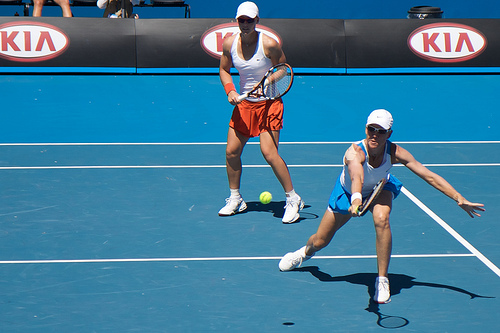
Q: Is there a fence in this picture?
A: No, there are no fences.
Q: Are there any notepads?
A: No, there are no notepads.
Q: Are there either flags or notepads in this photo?
A: No, there are no notepads or flags.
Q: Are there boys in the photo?
A: No, there are no boys.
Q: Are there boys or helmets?
A: No, there are no boys or helmets.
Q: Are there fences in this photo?
A: No, there are no fences.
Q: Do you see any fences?
A: No, there are no fences.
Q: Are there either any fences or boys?
A: No, there are no fences or boys.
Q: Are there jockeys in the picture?
A: No, there are no jockeys.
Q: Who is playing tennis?
A: The man is playing tennis.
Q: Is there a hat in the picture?
A: Yes, there is a hat.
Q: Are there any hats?
A: Yes, there is a hat.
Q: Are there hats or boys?
A: Yes, there is a hat.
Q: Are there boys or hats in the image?
A: Yes, there is a hat.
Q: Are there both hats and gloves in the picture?
A: No, there is a hat but no gloves.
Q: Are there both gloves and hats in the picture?
A: No, there is a hat but no gloves.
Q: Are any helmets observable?
A: No, there are no helmets.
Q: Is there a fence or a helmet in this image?
A: No, there are no helmets or fences.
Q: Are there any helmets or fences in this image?
A: No, there are no helmets or fences.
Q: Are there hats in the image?
A: Yes, there is a hat.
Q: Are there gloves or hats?
A: Yes, there is a hat.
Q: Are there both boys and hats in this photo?
A: No, there is a hat but no boys.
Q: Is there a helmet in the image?
A: No, there are no helmets.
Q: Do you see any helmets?
A: No, there are no helmets.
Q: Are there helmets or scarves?
A: No, there are no helmets or scarves.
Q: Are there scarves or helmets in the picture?
A: No, there are no helmets or scarves.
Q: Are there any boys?
A: No, there are no boys.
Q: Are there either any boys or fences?
A: No, there are no boys or fences.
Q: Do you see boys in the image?
A: No, there are no boys.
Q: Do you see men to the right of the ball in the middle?
A: Yes, there is a man to the right of the ball.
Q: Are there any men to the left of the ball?
A: No, the man is to the right of the ball.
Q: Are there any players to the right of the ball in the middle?
A: No, there is a man to the right of the ball.